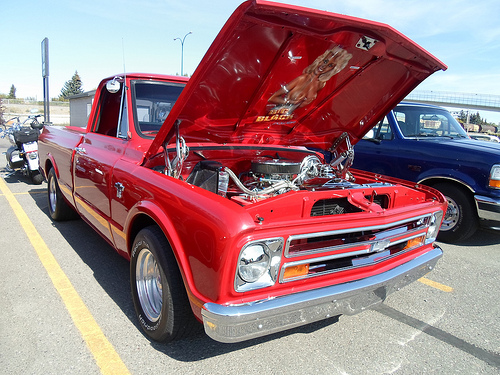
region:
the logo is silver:
[368, 233, 393, 257]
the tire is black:
[117, 225, 178, 349]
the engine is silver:
[225, 137, 375, 189]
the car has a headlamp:
[422, 212, 448, 250]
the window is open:
[91, 75, 127, 145]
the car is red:
[36, 49, 458, 334]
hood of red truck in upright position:
[142, 2, 449, 163]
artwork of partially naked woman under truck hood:
[266, 46, 352, 117]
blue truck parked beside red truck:
[352, 101, 499, 241]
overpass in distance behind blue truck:
[405, 87, 498, 110]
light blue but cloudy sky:
[2, 0, 499, 99]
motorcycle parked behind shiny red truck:
[0, 111, 48, 183]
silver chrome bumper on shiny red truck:
[202, 242, 442, 344]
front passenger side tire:
[125, 224, 192, 344]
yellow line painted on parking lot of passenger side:
[3, 192, 132, 374]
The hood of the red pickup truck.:
[167, 3, 443, 172]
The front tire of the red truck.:
[126, 222, 183, 341]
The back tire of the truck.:
[43, 164, 65, 222]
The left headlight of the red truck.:
[235, 246, 270, 281]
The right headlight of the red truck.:
[423, 215, 437, 246]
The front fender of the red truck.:
[200, 249, 452, 344]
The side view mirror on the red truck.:
[99, 72, 122, 92]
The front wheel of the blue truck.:
[424, 174, 474, 241]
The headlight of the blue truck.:
[485, 162, 498, 190]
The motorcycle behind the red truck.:
[3, 116, 50, 184]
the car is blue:
[358, 73, 497, 243]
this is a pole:
[34, 25, 66, 125]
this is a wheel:
[96, 210, 197, 367]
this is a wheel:
[37, 165, 77, 232]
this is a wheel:
[420, 175, 473, 242]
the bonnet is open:
[156, 120, 420, 228]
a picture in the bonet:
[253, 28, 361, 123]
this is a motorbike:
[0, 112, 65, 200]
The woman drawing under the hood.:
[263, 42, 352, 134]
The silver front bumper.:
[198, 251, 462, 328]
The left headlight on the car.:
[228, 237, 280, 287]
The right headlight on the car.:
[421, 204, 455, 256]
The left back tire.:
[34, 168, 66, 213]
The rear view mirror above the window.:
[102, 72, 129, 99]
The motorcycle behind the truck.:
[1, 110, 43, 177]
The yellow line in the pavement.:
[6, 187, 62, 279]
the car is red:
[26, 8, 447, 334]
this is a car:
[31, 5, 453, 335]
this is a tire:
[108, 223, 208, 340]